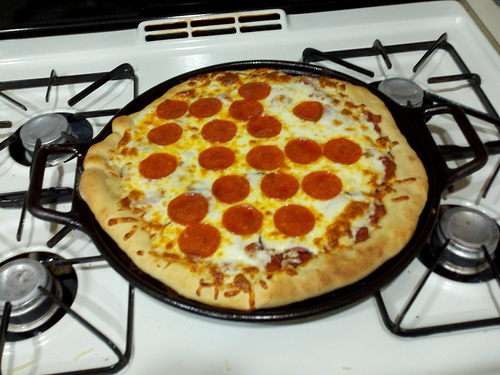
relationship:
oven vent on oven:
[129, 7, 291, 47] [1, 3, 497, 372]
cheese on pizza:
[279, 119, 369, 138] [53, 50, 452, 312]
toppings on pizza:
[198, 113, 288, 171] [77, 57, 443, 328]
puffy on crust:
[81, 143, 106, 211] [78, 120, 127, 246]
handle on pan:
[415, 86, 482, 187] [27, 57, 484, 324]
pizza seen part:
[77, 65, 426, 310] [241, 272, 282, 302]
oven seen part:
[1, 3, 497, 372] [137, 319, 393, 372]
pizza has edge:
[77, 57, 443, 328] [82, 166, 89, 175]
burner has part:
[369, 152, 499, 336] [397, 284, 422, 314]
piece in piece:
[135, 150, 180, 182] [135, 150, 180, 182]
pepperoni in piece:
[147, 123, 182, 143] [180, 206, 189, 211]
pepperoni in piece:
[231, 96, 263, 121] [343, 149, 349, 154]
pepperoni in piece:
[325, 136, 363, 163] [266, 147, 272, 156]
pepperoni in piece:
[247, 145, 286, 170] [243, 104, 245, 113]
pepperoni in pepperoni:
[169, 190, 205, 224] [147, 123, 182, 143]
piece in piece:
[234, 79, 278, 100] [257, 168, 306, 209]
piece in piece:
[161, 188, 211, 224] [161, 188, 211, 224]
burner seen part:
[0, 201, 137, 373] [26, 274, 71, 315]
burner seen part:
[350, 30, 484, 157] [412, 48, 452, 80]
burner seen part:
[1, 61, 138, 373] [17, 128, 42, 158]